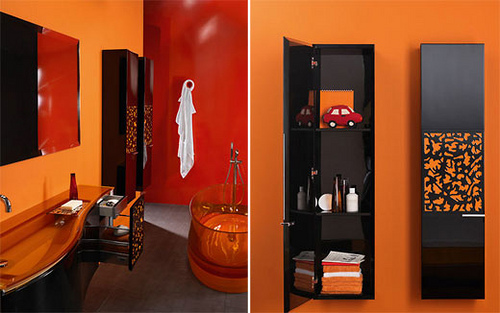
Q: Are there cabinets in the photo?
A: Yes, there is a cabinet.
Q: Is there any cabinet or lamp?
A: Yes, there is a cabinet.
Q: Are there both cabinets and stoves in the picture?
A: No, there is a cabinet but no stoves.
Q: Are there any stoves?
A: No, there are no stoves.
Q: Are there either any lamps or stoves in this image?
A: No, there are no stoves or lamps.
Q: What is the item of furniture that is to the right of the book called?
A: The piece of furniture is a cabinet.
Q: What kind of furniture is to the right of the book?
A: The piece of furniture is a cabinet.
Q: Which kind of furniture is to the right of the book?
A: The piece of furniture is a cabinet.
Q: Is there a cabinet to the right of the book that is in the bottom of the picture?
A: Yes, there is a cabinet to the right of the book.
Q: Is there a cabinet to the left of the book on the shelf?
A: No, the cabinet is to the right of the book.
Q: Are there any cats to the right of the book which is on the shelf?
A: No, there is a cabinet to the right of the book.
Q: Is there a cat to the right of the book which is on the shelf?
A: No, there is a cabinet to the right of the book.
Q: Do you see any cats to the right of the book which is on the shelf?
A: No, there is a cabinet to the right of the book.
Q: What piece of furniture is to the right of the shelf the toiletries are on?
A: The piece of furniture is a cabinet.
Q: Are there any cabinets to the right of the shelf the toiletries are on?
A: Yes, there is a cabinet to the right of the shelf.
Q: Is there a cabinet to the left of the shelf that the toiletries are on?
A: No, the cabinet is to the right of the shelf.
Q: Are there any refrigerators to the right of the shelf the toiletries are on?
A: No, there is a cabinet to the right of the shelf.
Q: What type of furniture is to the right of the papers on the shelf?
A: The piece of furniture is a cabinet.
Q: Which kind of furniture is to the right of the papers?
A: The piece of furniture is a cabinet.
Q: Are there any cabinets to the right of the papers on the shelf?
A: Yes, there is a cabinet to the right of the papers.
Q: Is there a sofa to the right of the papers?
A: No, there is a cabinet to the right of the papers.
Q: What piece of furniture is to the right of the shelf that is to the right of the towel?
A: The piece of furniture is a cabinet.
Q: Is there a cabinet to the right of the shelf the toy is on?
A: Yes, there is a cabinet to the right of the shelf.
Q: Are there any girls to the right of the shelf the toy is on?
A: No, there is a cabinet to the right of the shelf.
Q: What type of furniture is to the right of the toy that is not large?
A: The piece of furniture is a cabinet.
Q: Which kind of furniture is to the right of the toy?
A: The piece of furniture is a cabinet.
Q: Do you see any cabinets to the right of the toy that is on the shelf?
A: Yes, there is a cabinet to the right of the toy.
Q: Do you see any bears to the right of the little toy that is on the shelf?
A: No, there is a cabinet to the right of the toy.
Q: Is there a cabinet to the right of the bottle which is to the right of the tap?
A: Yes, there is a cabinet to the right of the bottle.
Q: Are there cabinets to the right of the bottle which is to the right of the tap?
A: Yes, there is a cabinet to the right of the bottle.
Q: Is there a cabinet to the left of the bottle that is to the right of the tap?
A: No, the cabinet is to the right of the bottle.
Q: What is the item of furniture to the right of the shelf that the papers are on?
A: The piece of furniture is a cabinet.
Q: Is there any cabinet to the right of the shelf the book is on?
A: Yes, there is a cabinet to the right of the shelf.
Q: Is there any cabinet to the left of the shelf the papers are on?
A: No, the cabinet is to the right of the shelf.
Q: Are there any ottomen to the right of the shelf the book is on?
A: No, there is a cabinet to the right of the shelf.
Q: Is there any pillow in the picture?
A: No, there are no pillows.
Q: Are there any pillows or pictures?
A: No, there are no pillows or pictures.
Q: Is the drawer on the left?
A: Yes, the drawer is on the left of the image.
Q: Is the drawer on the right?
A: No, the drawer is on the left of the image.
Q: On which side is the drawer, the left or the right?
A: The drawer is on the left of the image.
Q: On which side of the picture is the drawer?
A: The drawer is on the left of the image.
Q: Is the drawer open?
A: Yes, the drawer is open.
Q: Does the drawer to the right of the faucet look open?
A: Yes, the drawer is open.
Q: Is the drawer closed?
A: No, the drawer is open.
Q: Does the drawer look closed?
A: No, the drawer is open.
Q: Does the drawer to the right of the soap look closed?
A: No, the drawer is open.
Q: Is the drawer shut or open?
A: The drawer is open.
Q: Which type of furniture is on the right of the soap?
A: The piece of furniture is a drawer.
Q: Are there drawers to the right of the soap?
A: Yes, there is a drawer to the right of the soap.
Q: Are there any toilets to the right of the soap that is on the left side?
A: No, there is a drawer to the right of the soap.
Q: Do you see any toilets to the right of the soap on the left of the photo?
A: No, there is a drawer to the right of the soap.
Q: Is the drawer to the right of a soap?
A: Yes, the drawer is to the right of a soap.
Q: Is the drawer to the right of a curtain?
A: No, the drawer is to the right of a soap.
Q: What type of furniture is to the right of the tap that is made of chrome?
A: The piece of furniture is a drawer.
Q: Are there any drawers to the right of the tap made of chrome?
A: Yes, there is a drawer to the right of the tap.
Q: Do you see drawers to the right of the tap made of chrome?
A: Yes, there is a drawer to the right of the tap.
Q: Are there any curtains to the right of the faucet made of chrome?
A: No, there is a drawer to the right of the faucet.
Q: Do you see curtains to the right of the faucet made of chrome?
A: No, there is a drawer to the right of the faucet.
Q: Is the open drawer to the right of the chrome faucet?
A: Yes, the drawer is to the right of the faucet.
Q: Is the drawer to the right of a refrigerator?
A: No, the drawer is to the right of the faucet.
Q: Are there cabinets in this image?
A: Yes, there is a cabinet.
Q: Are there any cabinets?
A: Yes, there is a cabinet.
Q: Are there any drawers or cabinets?
A: Yes, there is a cabinet.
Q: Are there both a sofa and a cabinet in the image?
A: No, there is a cabinet but no sofas.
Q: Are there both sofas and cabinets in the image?
A: No, there is a cabinet but no sofas.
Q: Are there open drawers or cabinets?
A: Yes, there is an open cabinet.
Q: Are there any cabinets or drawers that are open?
A: Yes, the cabinet is open.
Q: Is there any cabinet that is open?
A: Yes, there is an open cabinet.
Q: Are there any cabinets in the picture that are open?
A: Yes, there is a cabinet that is open.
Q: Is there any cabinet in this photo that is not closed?
A: Yes, there is a open cabinet.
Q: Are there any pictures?
A: No, there are no pictures.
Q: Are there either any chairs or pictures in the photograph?
A: No, there are no pictures or chairs.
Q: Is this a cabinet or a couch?
A: This is a cabinet.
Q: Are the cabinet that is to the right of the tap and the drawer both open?
A: Yes, both the cabinet and the drawer are open.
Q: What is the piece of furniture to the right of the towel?
A: The piece of furniture is a cabinet.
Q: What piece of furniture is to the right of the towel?
A: The piece of furniture is a cabinet.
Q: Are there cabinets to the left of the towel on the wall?
A: No, the cabinet is to the right of the towel.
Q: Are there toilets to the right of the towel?
A: No, there is a cabinet to the right of the towel.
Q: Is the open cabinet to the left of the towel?
A: No, the cabinet is to the right of the towel.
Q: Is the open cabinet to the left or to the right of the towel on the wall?
A: The cabinet is to the right of the towel.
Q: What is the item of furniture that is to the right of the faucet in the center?
A: The piece of furniture is a cabinet.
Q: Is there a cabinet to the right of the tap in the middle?
A: Yes, there is a cabinet to the right of the faucet.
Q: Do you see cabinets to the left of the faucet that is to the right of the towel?
A: No, the cabinet is to the right of the tap.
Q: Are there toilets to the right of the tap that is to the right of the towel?
A: No, there is a cabinet to the right of the faucet.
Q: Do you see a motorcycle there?
A: No, there are no motorcycles.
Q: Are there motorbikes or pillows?
A: No, there are no motorbikes or pillows.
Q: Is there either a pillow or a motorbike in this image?
A: No, there are no motorcycles or pillows.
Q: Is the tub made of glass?
A: Yes, the tub is made of glass.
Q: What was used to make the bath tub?
A: The bath tub is made of glass.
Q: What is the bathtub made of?
A: The bath tub is made of glass.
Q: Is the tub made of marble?
A: No, the tub is made of glass.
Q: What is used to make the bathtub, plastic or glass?
A: The bathtub is made of glass.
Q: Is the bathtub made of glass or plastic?
A: The bathtub is made of glass.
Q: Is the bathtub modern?
A: Yes, the bathtub is modern.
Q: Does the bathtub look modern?
A: Yes, the bathtub is modern.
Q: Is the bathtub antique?
A: No, the bathtub is modern.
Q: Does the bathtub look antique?
A: No, the bathtub is modern.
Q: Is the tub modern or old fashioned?
A: The tub is modern.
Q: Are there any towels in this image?
A: Yes, there is a towel.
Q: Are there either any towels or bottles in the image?
A: Yes, there is a towel.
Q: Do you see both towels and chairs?
A: No, there is a towel but no chairs.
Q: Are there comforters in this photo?
A: No, there are no comforters.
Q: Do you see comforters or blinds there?
A: No, there are no comforters or blinds.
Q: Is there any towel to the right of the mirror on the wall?
A: Yes, there is a towel to the right of the mirror.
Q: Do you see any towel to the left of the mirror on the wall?
A: No, the towel is to the right of the mirror.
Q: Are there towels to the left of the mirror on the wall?
A: No, the towel is to the right of the mirror.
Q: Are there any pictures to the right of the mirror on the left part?
A: No, there is a towel to the right of the mirror.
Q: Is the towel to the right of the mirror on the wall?
A: Yes, the towel is to the right of the mirror.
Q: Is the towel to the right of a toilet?
A: No, the towel is to the right of the mirror.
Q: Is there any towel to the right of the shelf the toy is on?
A: No, the towel is to the left of the shelf.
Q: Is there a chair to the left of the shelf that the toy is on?
A: No, there is a towel to the left of the shelf.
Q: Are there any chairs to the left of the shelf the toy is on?
A: No, there is a towel to the left of the shelf.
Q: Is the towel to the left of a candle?
A: No, the towel is to the left of a shelf.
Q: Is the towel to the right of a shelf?
A: No, the towel is to the left of a shelf.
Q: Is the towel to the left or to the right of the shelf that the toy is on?
A: The towel is to the left of the shelf.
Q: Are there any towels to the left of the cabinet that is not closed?
A: Yes, there is a towel to the left of the cabinet.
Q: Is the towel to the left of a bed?
A: No, the towel is to the left of the cabinet.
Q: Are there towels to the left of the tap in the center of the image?
A: Yes, there is a towel to the left of the tap.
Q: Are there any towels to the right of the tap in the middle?
A: No, the towel is to the left of the faucet.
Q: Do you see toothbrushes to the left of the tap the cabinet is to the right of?
A: No, there is a towel to the left of the tap.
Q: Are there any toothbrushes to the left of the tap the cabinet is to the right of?
A: No, there is a towel to the left of the tap.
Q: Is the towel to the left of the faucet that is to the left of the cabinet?
A: Yes, the towel is to the left of the tap.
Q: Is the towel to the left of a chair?
A: No, the towel is to the left of the tap.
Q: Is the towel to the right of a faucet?
A: No, the towel is to the left of a faucet.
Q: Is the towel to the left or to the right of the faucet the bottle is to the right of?
A: The towel is to the left of the tap.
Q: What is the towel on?
A: The towel is on the wall.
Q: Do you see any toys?
A: Yes, there is a toy.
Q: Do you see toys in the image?
A: Yes, there is a toy.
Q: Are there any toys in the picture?
A: Yes, there is a toy.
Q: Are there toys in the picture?
A: Yes, there is a toy.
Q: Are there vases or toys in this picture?
A: Yes, there is a toy.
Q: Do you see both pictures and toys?
A: No, there is a toy but no pictures.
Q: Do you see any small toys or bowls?
A: Yes, there is a small toy.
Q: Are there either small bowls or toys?
A: Yes, there is a small toy.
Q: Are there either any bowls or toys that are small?
A: Yes, the toy is small.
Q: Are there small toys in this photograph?
A: Yes, there is a small toy.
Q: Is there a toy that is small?
A: Yes, there is a toy that is small.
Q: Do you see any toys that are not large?
A: Yes, there is a small toy.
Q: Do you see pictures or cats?
A: No, there are no pictures or cats.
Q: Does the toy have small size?
A: Yes, the toy is small.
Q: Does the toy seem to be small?
A: Yes, the toy is small.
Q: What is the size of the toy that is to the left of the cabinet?
A: The toy is small.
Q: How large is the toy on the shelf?
A: The toy is small.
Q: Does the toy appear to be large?
A: No, the toy is small.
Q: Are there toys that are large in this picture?
A: No, there is a toy but it is small.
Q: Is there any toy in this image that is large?
A: No, there is a toy but it is small.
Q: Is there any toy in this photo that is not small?
A: No, there is a toy but it is small.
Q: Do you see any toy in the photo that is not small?
A: No, there is a toy but it is small.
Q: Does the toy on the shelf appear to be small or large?
A: The toy is small.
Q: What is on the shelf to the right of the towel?
A: The toy is on the shelf.